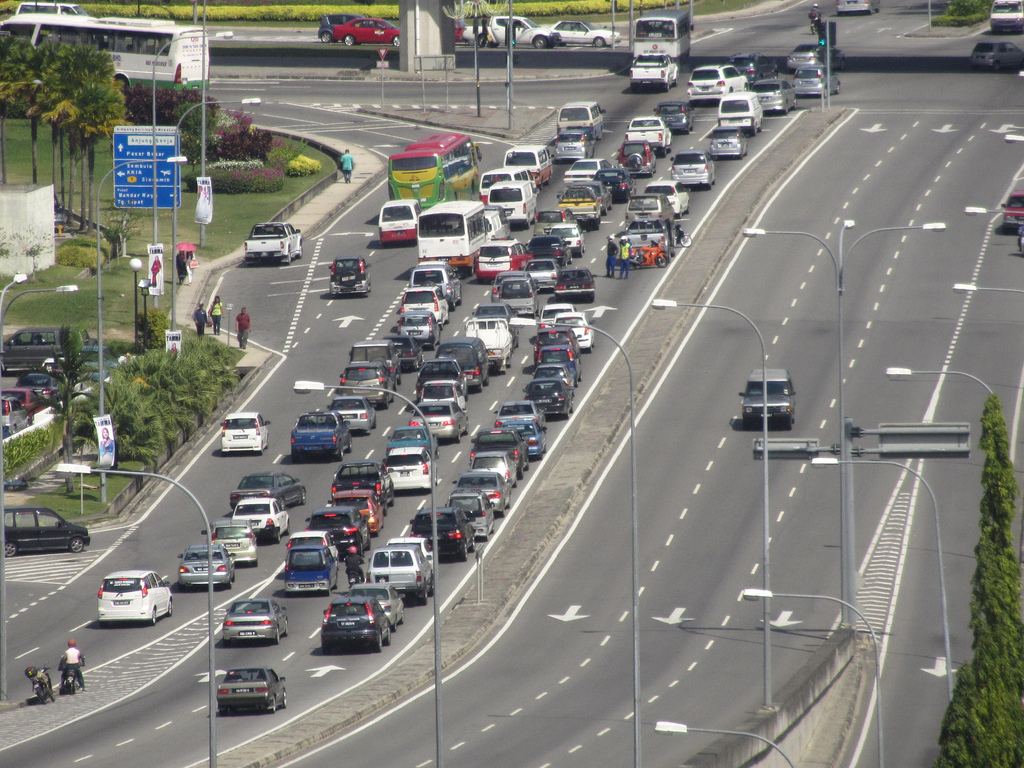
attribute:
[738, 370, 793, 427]
van — GREY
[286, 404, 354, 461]
truck — blue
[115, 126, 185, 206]
sign — blue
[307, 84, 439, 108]
arrow — white 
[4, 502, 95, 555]
van — black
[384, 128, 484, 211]
bus — red, yellow, green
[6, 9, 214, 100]
bus — very big, white, green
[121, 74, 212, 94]
bottom — green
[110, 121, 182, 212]
traffic sign — blue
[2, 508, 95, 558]
minivan — crappy, black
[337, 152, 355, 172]
shirt — sea foam green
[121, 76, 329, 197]
flower display — nicely manicured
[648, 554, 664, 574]
line — white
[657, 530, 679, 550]
line — white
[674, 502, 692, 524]
line — white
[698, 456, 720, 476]
line — white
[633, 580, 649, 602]
line — white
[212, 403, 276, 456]
car — white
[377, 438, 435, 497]
car — white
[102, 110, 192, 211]
sign — large, blue